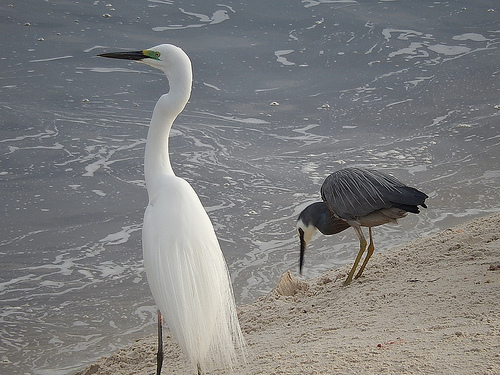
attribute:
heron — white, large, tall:
[80, 32, 256, 375]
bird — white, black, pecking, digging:
[279, 160, 432, 299]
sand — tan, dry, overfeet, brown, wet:
[43, 211, 498, 374]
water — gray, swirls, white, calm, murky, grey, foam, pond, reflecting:
[2, 3, 498, 375]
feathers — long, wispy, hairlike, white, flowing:
[166, 286, 253, 373]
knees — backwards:
[357, 236, 376, 261]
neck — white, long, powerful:
[134, 84, 188, 184]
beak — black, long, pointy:
[93, 47, 151, 66]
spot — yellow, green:
[141, 48, 162, 64]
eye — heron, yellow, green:
[152, 49, 165, 65]